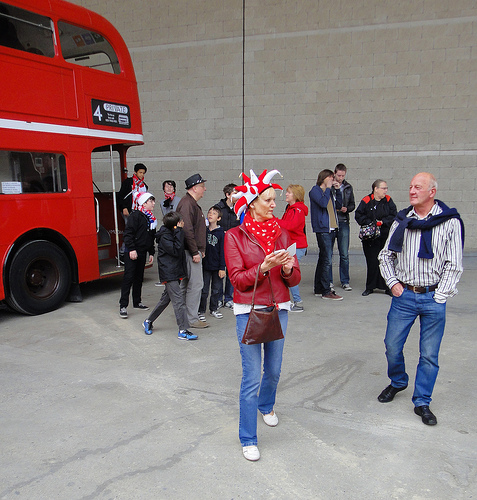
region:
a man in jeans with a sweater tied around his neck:
[379, 164, 471, 445]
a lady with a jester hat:
[214, 169, 316, 466]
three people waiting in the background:
[311, 160, 399, 313]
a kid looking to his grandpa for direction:
[183, 173, 225, 335]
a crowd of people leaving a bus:
[49, 94, 468, 316]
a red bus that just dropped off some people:
[2, 0, 132, 316]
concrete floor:
[23, 327, 299, 485]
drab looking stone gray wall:
[152, 79, 474, 185]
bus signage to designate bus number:
[66, 81, 138, 133]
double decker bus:
[12, 5, 148, 270]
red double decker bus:
[23, 29, 149, 306]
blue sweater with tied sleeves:
[389, 193, 462, 262]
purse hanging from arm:
[241, 259, 294, 353]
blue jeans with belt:
[376, 275, 453, 407]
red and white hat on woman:
[221, 167, 289, 220]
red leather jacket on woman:
[219, 220, 303, 314]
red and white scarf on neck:
[239, 212, 290, 258]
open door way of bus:
[84, 134, 150, 286]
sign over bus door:
[75, 92, 143, 158]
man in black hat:
[181, 167, 212, 217]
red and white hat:
[214, 153, 292, 227]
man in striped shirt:
[388, 157, 475, 274]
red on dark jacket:
[353, 169, 398, 260]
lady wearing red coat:
[219, 173, 302, 303]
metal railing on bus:
[98, 140, 130, 275]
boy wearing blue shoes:
[136, 211, 209, 368]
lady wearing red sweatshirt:
[274, 173, 339, 317]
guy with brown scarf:
[309, 159, 347, 315]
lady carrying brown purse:
[229, 189, 293, 371]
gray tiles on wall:
[274, 81, 406, 133]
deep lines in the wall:
[221, 140, 319, 169]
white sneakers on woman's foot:
[222, 436, 285, 461]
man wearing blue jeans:
[377, 279, 454, 385]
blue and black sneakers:
[167, 325, 211, 341]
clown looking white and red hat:
[222, 154, 294, 209]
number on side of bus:
[78, 84, 138, 128]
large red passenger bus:
[56, 90, 147, 296]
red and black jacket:
[358, 190, 398, 224]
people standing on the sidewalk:
[133, 154, 456, 379]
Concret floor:
[9, 317, 240, 494]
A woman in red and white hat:
[210, 140, 324, 306]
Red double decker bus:
[1, 1, 197, 316]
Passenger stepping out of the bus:
[39, 44, 458, 431]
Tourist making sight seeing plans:
[91, 115, 465, 445]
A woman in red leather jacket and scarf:
[216, 141, 334, 453]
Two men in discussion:
[305, 155, 364, 311]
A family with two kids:
[108, 174, 225, 343]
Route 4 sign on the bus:
[52, 84, 150, 150]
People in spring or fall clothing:
[93, 127, 473, 368]